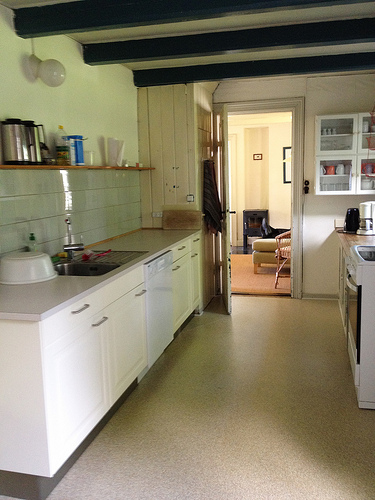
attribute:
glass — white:
[319, 118, 353, 150]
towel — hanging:
[203, 156, 222, 236]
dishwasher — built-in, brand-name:
[120, 237, 198, 398]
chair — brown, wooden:
[277, 221, 299, 292]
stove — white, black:
[342, 245, 374, 415]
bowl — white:
[0, 240, 55, 290]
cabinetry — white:
[40, 232, 229, 392]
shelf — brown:
[0, 160, 154, 172]